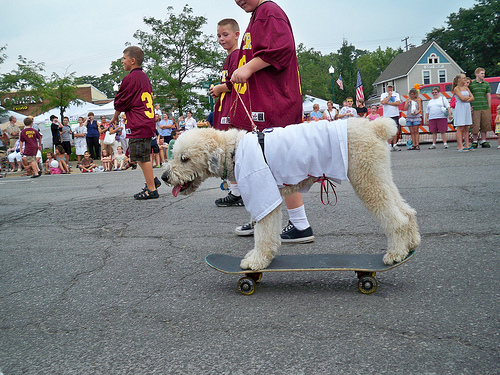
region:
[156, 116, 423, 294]
this patient dog is riding a skateboard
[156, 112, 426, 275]
this patient dog is wearing a ridiculous doggie t-shirt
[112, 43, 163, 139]
this kid is wearing a jersey with the number 3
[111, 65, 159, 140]
this kid is wearing a maroon jersey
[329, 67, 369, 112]
the American flags may mean this is a national holiday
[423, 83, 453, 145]
this lady looks like she should walk more often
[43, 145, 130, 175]
child spectators sit along the curb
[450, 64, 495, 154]
this lovely couple is watching the parade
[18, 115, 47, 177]
another kid in a maroon jersey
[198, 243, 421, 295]
the patient dog's skateboard is black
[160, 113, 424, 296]
Dog riding a skateboard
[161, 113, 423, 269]
Dog wearing a white t-shirt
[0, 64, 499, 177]
People standing along the side of the road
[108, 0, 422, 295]
Boys and dog in the street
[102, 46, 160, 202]
Boy with maroon jersey with the number 3 on it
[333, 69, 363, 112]
Two American flags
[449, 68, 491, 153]
Man and woman standing along the roadside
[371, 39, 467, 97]
Tan and blue house in the background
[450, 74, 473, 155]
Woman wearing a white sundress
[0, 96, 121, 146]
White tents behind the people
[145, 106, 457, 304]
a dog on a skateboard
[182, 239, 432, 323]
a black skateboard with dog on it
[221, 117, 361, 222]
a white shirt on the dog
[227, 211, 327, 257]
black and white sneakers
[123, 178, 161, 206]
black sandals on feet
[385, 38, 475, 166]
a tan and blue house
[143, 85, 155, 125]
a yellow 3 on shirt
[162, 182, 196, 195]
tongue hanging out of mouth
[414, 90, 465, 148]
a woman in pink shorts and white top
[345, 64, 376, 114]
an american flag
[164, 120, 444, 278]
dog in a white shirt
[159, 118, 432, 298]
dog on a skateboard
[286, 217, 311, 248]
black sneaker on a boy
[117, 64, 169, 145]
maroon jersey with yellow number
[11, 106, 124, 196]
people watching a parade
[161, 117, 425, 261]
tan dog in a white shirt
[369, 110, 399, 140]
short tail of a tan dog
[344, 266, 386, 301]
back wheel of a skateboard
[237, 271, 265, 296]
front wheels of a skateboard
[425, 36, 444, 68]
windows on the top of a house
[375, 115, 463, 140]
an orange and white stripped board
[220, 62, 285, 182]
a red leash on dog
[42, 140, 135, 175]
children sitting on the curb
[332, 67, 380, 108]
two american flags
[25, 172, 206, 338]
cracks in the road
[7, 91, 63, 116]
white and yellow sign on building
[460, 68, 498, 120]
a green striped shirt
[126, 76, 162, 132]
Number 3 on shirt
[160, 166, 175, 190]
black nose of dog